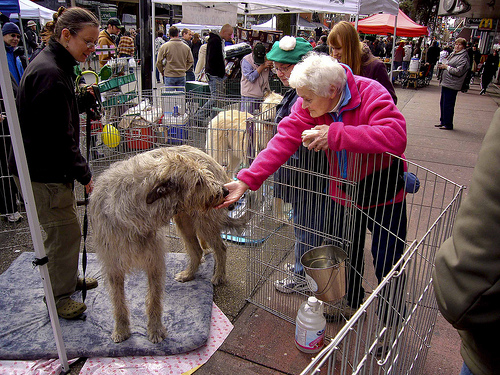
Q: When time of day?
A: Daytime.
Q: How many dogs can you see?
A: 2.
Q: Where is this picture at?
A: Dog show.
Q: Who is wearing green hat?
A: Woman.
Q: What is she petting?
A: Dog.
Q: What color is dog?
A: Brown.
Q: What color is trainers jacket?
A: Black.